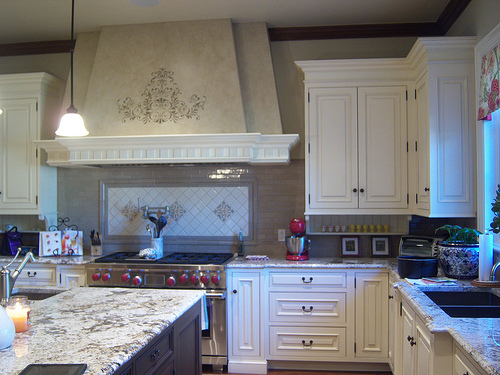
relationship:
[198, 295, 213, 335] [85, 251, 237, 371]
towel hanging on oven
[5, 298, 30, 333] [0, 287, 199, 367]
candle on counter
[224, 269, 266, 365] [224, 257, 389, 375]
cupboard under cabinets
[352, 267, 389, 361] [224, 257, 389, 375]
cupboard under cabinets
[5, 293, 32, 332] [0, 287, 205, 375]
candle on counter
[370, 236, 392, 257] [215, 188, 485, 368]
many boats above counter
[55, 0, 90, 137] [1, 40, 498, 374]
fixture in kitchen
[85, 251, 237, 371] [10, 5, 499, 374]
oven in kitchen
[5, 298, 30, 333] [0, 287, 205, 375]
candle on a counter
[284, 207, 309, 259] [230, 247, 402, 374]
coffee pot on a counter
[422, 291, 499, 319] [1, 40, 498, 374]
basin in a kitchen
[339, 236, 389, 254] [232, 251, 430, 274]
frames on countertop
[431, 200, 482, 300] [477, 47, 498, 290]
plant by window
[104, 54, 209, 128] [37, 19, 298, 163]
decoration on a hood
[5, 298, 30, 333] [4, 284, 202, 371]
candle on counter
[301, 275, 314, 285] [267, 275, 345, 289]
handles on drawers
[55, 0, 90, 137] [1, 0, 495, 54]
fixture hanging from ceiling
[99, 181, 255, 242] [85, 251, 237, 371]
tiles above oven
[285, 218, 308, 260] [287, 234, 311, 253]
coffee pot with bowl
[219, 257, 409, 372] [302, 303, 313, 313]
cabinets with handles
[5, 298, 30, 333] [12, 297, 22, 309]
candle with a flame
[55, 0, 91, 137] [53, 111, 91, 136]
fixture with light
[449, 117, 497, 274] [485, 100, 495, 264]
light coming in through window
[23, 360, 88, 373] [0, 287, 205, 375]
tablet on counter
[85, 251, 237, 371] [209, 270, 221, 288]
oven has knobs